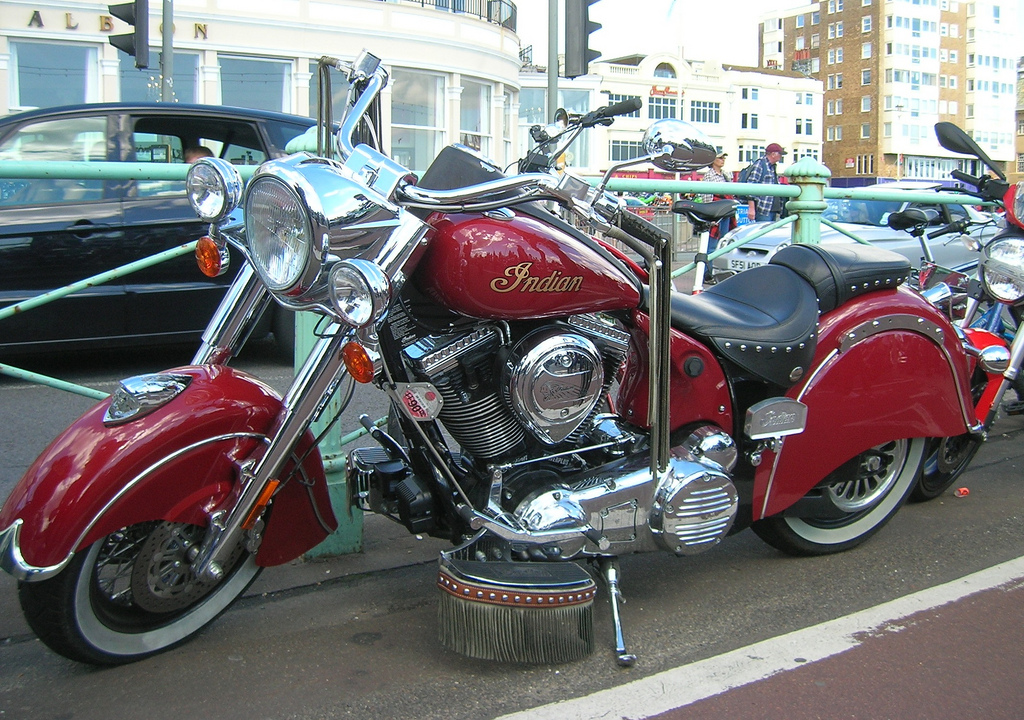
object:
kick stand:
[592, 557, 638, 667]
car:
[0, 102, 339, 366]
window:
[118, 46, 196, 103]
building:
[0, 0, 524, 178]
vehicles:
[710, 181, 1004, 286]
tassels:
[646, 239, 673, 475]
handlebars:
[605, 208, 674, 473]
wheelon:
[0, 362, 335, 670]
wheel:
[746, 438, 931, 558]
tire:
[12, 519, 263, 669]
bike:
[2, 68, 1007, 670]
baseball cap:
[765, 143, 788, 155]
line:
[495, 553, 1024, 720]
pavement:
[0, 214, 1024, 719]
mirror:
[934, 122, 977, 155]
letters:
[490, 262, 583, 292]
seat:
[642, 263, 819, 389]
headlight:
[238, 167, 323, 297]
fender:
[0, 364, 340, 583]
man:
[731, 143, 787, 223]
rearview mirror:
[642, 118, 717, 171]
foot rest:
[433, 558, 596, 666]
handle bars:
[317, 48, 672, 270]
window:
[649, 97, 675, 119]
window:
[391, 67, 446, 129]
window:
[691, 101, 719, 124]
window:
[742, 113, 758, 129]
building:
[519, 46, 824, 177]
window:
[796, 119, 812, 136]